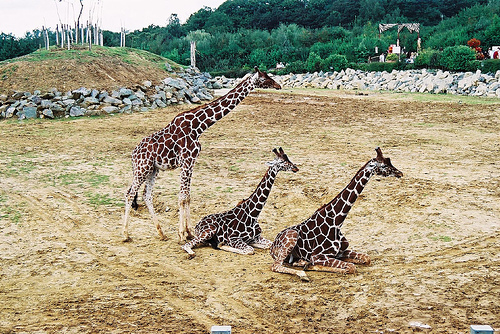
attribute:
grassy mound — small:
[5, 51, 170, 86]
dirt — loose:
[272, 283, 433, 325]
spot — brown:
[179, 119, 193, 136]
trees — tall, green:
[247, 22, 343, 69]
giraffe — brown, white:
[270, 148, 402, 280]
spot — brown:
[313, 217, 330, 239]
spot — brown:
[315, 221, 330, 238]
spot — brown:
[312, 231, 326, 247]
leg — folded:
[314, 257, 359, 273]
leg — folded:
[340, 249, 372, 262]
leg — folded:
[269, 259, 309, 282]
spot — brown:
[205, 117, 214, 124]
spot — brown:
[248, 207, 262, 218]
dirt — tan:
[61, 88, 475, 298]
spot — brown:
[324, 207, 333, 214]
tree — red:
[464, 36, 483, 58]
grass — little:
[10, 144, 122, 226]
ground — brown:
[2, 95, 494, 331]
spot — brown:
[254, 186, 266, 196]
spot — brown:
[294, 226, 320, 253]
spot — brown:
[160, 137, 177, 150]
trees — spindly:
[27, 7, 120, 52]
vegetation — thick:
[0, 0, 499, 74]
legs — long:
[177, 140, 201, 232]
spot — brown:
[248, 195, 262, 206]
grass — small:
[0, 147, 123, 224]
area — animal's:
[0, 42, 500, 332]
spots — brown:
[122, 67, 281, 202]